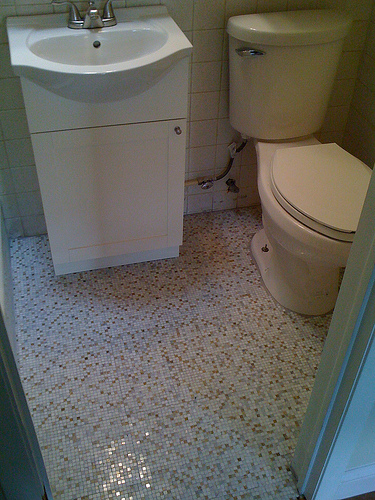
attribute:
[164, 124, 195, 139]
knob — silver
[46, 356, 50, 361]
tile — small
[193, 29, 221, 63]
tile — white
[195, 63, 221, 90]
tile — white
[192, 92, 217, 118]
tile — white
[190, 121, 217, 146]
tile — white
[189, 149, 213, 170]
tile — white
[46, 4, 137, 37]
faucet — silver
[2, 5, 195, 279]
sink — white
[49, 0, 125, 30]
faucet — on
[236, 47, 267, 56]
handle — silver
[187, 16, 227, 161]
tile — white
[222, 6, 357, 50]
lid — beige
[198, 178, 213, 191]
valve — oval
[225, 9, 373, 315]
toilet — white